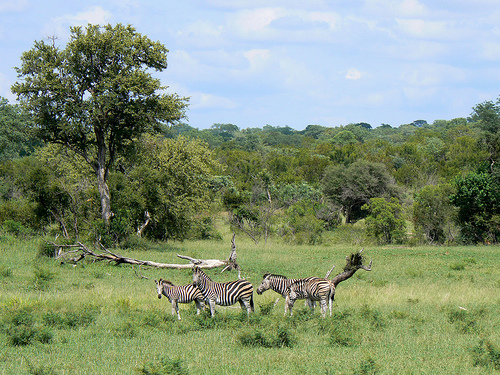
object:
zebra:
[154, 276, 214, 319]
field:
[1, 235, 499, 372]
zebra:
[188, 266, 256, 320]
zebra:
[257, 270, 336, 322]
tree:
[44, 202, 246, 284]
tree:
[11, 23, 192, 245]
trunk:
[91, 161, 118, 240]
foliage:
[356, 191, 400, 242]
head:
[153, 278, 164, 300]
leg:
[206, 299, 217, 321]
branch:
[96, 240, 121, 257]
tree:
[318, 158, 407, 226]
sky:
[0, 1, 499, 129]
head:
[189, 265, 202, 288]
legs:
[325, 296, 335, 317]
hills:
[376, 112, 452, 191]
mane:
[160, 279, 175, 286]